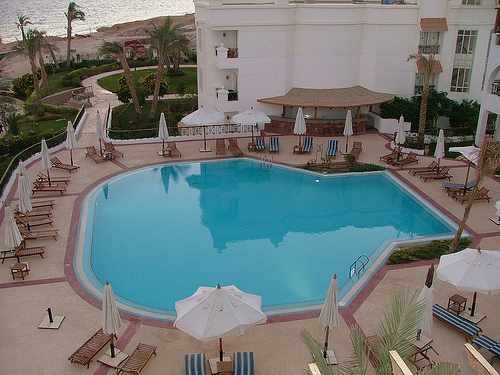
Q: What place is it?
A: It is a swimming pool.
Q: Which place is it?
A: It is a swimming pool.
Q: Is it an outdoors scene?
A: Yes, it is outdoors.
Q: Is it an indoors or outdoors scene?
A: It is outdoors.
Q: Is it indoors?
A: No, it is outdoors.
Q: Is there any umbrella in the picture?
A: Yes, there is an umbrella.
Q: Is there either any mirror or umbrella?
A: Yes, there is an umbrella.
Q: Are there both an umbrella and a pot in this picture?
A: No, there is an umbrella but no pots.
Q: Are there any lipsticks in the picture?
A: No, there are no lipsticks.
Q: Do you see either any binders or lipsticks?
A: No, there are no lipsticks or binders.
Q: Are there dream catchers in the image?
A: No, there are no dream catchers.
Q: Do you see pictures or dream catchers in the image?
A: No, there are no dream catchers or pictures.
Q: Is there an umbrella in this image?
A: Yes, there is an umbrella.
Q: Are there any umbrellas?
A: Yes, there is an umbrella.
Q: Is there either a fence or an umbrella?
A: Yes, there is an umbrella.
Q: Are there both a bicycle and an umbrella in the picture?
A: No, there is an umbrella but no bicycles.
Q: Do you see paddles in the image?
A: No, there are no paddles.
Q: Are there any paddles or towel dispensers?
A: No, there are no paddles or towel dispensers.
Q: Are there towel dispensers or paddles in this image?
A: No, there are no paddles or towel dispensers.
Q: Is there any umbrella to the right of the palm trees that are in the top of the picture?
A: Yes, there is an umbrella to the right of the palm trees.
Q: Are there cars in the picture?
A: No, there are no cars.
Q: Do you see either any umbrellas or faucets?
A: Yes, there is an umbrella.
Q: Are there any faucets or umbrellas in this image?
A: Yes, there is an umbrella.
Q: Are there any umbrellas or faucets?
A: Yes, there is an umbrella.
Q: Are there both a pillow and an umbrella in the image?
A: No, there is an umbrella but no pillows.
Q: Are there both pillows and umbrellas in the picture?
A: No, there is an umbrella but no pillows.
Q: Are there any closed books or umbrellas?
A: Yes, there is a closed umbrella.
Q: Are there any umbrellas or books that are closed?
A: Yes, the umbrella is closed.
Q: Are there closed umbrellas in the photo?
A: Yes, there is a closed umbrella.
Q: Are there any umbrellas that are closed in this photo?
A: Yes, there is a closed umbrella.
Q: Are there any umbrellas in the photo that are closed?
A: Yes, there is an umbrella that is closed.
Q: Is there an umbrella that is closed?
A: Yes, there is an umbrella that is closed.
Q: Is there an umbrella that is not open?
A: Yes, there is an closed umbrella.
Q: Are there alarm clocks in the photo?
A: No, there are no alarm clocks.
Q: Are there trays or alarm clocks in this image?
A: No, there are no alarm clocks or trays.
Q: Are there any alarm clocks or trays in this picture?
A: No, there are no alarm clocks or trays.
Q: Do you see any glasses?
A: No, there are no glasses.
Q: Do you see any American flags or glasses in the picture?
A: No, there are no glasses or American flags.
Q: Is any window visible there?
A: Yes, there are windows.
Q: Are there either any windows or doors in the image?
A: Yes, there are windows.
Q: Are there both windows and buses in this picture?
A: No, there are windows but no buses.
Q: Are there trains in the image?
A: No, there are no trains.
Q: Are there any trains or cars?
A: No, there are no trains or cars.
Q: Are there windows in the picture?
A: Yes, there are windows.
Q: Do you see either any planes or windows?
A: Yes, there are windows.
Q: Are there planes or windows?
A: Yes, there are windows.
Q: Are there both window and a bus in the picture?
A: No, there are windows but no buses.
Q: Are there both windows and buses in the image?
A: No, there are windows but no buses.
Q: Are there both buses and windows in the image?
A: No, there are windows but no buses.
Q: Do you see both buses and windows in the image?
A: No, there are windows but no buses.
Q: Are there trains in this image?
A: No, there are no trains.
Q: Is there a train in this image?
A: No, there are no trains.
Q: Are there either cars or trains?
A: No, there are no trains or cars.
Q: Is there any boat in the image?
A: No, there are no boats.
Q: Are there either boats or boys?
A: No, there are no boats or boys.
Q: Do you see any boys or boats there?
A: No, there are no boats or boys.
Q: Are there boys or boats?
A: No, there are no boats or boys.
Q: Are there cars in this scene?
A: No, there are no cars.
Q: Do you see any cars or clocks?
A: No, there are no cars or clocks.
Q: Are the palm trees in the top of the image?
A: Yes, the palm trees are in the top of the image.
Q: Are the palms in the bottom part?
A: No, the palms are in the top of the image.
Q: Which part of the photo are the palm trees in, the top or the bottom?
A: The palm trees are in the top of the image.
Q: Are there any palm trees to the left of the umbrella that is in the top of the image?
A: Yes, there are palm trees to the left of the umbrella.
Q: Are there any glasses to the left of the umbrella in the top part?
A: No, there are palm trees to the left of the umbrella.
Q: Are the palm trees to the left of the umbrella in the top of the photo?
A: Yes, the palm trees are to the left of the umbrella.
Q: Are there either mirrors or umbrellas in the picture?
A: Yes, there is an umbrella.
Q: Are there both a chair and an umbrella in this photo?
A: Yes, there are both an umbrella and a chair.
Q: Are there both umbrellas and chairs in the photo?
A: Yes, there are both an umbrella and a chair.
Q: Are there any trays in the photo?
A: No, there are no trays.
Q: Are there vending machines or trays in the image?
A: No, there are no trays or vending machines.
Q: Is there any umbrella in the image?
A: Yes, there is an umbrella.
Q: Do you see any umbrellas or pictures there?
A: Yes, there is an umbrella.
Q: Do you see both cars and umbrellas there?
A: No, there is an umbrella but no cars.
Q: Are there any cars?
A: No, there are no cars.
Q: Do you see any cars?
A: No, there are no cars.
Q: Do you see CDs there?
A: No, there are no cds.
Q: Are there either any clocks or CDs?
A: No, there are no CDs or clocks.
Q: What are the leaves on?
A: The leaves are on the tree.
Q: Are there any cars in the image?
A: No, there are no cars.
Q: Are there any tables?
A: Yes, there is a table.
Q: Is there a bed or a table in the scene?
A: Yes, there is a table.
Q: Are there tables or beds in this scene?
A: Yes, there is a table.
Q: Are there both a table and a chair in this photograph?
A: Yes, there are both a table and a chair.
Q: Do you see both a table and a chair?
A: Yes, there are both a table and a chair.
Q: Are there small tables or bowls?
A: Yes, there is a small table.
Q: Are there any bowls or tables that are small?
A: Yes, the table is small.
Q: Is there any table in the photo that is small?
A: Yes, there is a small table.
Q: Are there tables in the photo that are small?
A: Yes, there is a table that is small.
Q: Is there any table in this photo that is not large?
A: Yes, there is a small table.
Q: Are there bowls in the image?
A: No, there are no bowls.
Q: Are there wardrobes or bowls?
A: No, there are no bowls or wardrobes.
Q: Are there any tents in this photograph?
A: No, there are no tents.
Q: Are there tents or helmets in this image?
A: No, there are no tents or helmets.